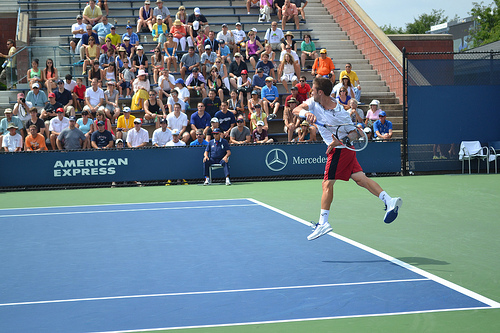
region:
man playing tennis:
[282, 65, 409, 265]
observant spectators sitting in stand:
[51, 49, 123, 114]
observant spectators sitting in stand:
[192, 58, 247, 88]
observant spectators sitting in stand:
[214, 32, 248, 70]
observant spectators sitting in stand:
[157, 53, 221, 114]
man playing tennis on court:
[277, 92, 420, 259]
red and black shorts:
[317, 144, 371, 189]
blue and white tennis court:
[99, 216, 254, 330]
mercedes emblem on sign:
[264, 142, 296, 171]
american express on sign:
[55, 148, 160, 201]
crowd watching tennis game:
[78, 23, 233, 105]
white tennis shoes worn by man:
[296, 195, 408, 248]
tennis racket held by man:
[295, 103, 378, 157]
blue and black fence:
[400, 49, 490, 173]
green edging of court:
[408, 177, 482, 298]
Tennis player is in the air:
[279, 68, 405, 261]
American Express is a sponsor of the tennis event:
[14, 140, 207, 182]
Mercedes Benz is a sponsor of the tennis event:
[217, 143, 344, 186]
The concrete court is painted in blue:
[6, 201, 496, 328]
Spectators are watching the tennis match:
[7, 7, 385, 147]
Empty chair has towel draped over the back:
[456, 133, 498, 175]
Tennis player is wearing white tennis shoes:
[292, 191, 424, 249]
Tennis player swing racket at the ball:
[272, 103, 385, 179]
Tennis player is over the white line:
[289, 68, 425, 296]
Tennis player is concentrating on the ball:
[239, 66, 481, 330]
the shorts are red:
[313, 138, 370, 196]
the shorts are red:
[315, 143, 370, 185]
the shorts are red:
[320, 138, 374, 192]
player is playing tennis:
[274, 76, 411, 284]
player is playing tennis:
[283, 73, 405, 253]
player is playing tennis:
[272, 60, 409, 262]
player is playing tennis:
[273, 60, 407, 242]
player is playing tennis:
[285, 74, 400, 251]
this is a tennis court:
[21, 23, 498, 305]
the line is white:
[67, 251, 151, 305]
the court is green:
[450, 204, 490, 241]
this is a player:
[234, 83, 484, 315]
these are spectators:
[42, 13, 242, 127]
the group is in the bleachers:
[48, 4, 236, 178]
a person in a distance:
[201, 121, 232, 183]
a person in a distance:
[165, 129, 186, 164]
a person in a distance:
[189, 128, 221, 167]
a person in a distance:
[55, 111, 95, 158]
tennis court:
[131, 235, 237, 285]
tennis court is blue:
[93, 218, 158, 261]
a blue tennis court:
[114, 248, 159, 286]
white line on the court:
[126, 285, 178, 300]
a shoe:
[379, 192, 400, 226]